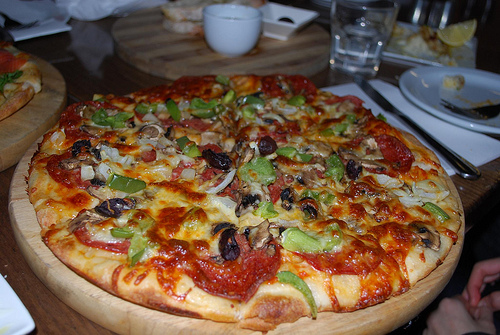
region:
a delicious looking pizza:
[14, 55, 481, 316]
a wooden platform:
[0, 199, 67, 305]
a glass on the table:
[323, 3, 405, 73]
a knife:
[358, 70, 478, 173]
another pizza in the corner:
[0, 41, 42, 108]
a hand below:
[466, 250, 497, 332]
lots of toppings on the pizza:
[75, 76, 421, 269]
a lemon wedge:
[427, 14, 480, 48]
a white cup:
[202, 0, 287, 60]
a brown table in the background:
[63, 43, 111, 93]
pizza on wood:
[66, 71, 421, 333]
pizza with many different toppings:
[118, 120, 378, 273]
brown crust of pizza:
[82, 237, 157, 293]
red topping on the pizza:
[174, 237, 274, 314]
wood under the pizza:
[68, 283, 125, 323]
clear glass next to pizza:
[313, 8, 404, 69]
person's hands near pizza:
[430, 261, 497, 331]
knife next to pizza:
[350, 77, 489, 180]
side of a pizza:
[0, 54, 62, 121]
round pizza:
[60, 91, 422, 314]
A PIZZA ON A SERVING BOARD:
[3, 70, 473, 325]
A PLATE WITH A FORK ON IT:
[397, 55, 494, 135]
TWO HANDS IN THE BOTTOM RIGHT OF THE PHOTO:
[417, 250, 494, 330]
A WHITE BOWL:
[195, 0, 266, 57]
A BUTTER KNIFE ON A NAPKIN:
[325, 60, 495, 180]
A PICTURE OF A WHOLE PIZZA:
[7, 34, 484, 332]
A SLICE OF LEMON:
[431, 13, 483, 53]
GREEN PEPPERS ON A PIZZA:
[99, 164, 150, 265]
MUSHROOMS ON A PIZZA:
[231, 177, 296, 255]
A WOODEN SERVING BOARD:
[100, 5, 349, 82]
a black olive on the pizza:
[216, 225, 241, 261]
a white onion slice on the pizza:
[206, 165, 240, 201]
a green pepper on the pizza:
[106, 172, 148, 196]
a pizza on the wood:
[23, 67, 468, 334]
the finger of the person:
[463, 256, 497, 310]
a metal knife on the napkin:
[348, 68, 485, 185]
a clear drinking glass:
[323, 1, 400, 78]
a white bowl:
[201, 2, 262, 61]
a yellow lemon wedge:
[434, 16, 479, 50]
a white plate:
[398, 60, 498, 146]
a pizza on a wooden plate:
[36, 72, 470, 327]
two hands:
[433, 267, 495, 334]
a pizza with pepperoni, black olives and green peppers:
[63, 72, 424, 302]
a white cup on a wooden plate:
[200, 6, 268, 56]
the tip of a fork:
[443, 94, 498, 119]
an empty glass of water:
[325, 2, 405, 70]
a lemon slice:
[440, 18, 485, 48]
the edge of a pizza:
[1, 30, 50, 143]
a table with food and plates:
[5, 6, 483, 331]